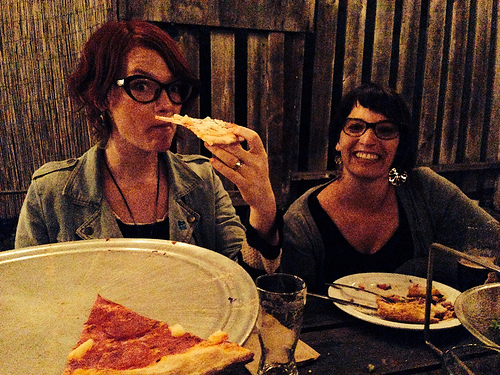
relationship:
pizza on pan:
[68, 293, 255, 375] [2, 238, 260, 374]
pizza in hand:
[156, 115, 246, 145] [205, 127, 275, 208]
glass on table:
[257, 273, 308, 374] [301, 304, 475, 375]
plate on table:
[329, 271, 465, 329] [301, 304, 475, 375]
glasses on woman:
[116, 75, 195, 105] [14, 19, 282, 278]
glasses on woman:
[341, 117, 404, 140] [280, 84, 499, 274]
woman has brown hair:
[14, 19, 282, 278] [69, 19, 127, 151]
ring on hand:
[234, 158, 244, 170] [205, 127, 275, 208]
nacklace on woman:
[99, 153, 141, 239] [14, 19, 282, 278]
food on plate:
[377, 284, 455, 323] [329, 271, 465, 329]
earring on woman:
[388, 168, 408, 187] [280, 84, 499, 274]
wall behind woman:
[1, 2, 498, 213] [14, 19, 282, 278]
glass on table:
[459, 219, 500, 274] [301, 304, 475, 375]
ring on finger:
[234, 158, 244, 170] [204, 139, 246, 173]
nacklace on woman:
[99, 153, 165, 239] [14, 19, 282, 278]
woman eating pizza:
[14, 19, 282, 278] [156, 115, 246, 145]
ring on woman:
[234, 158, 244, 170] [14, 19, 282, 278]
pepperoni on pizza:
[105, 311, 155, 340] [68, 293, 255, 375]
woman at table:
[14, 19, 282, 278] [301, 304, 475, 375]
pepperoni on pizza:
[105, 341, 150, 371] [68, 293, 255, 375]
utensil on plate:
[310, 293, 378, 310] [329, 271, 465, 329]